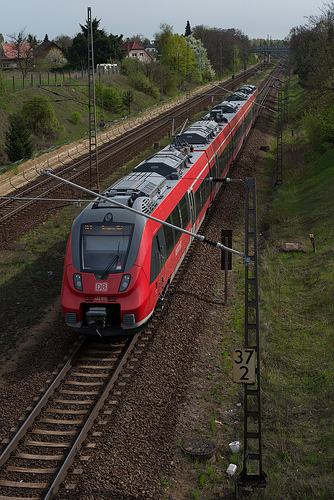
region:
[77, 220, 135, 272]
Windshield on a train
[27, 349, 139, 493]
Railroad track in the rocks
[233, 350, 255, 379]
Black numbers on a sign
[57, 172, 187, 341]
Front end of a train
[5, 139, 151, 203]
Railroad tracks in the rocks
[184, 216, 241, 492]
Patches of green grass in the dirt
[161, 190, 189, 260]
Windows on a train car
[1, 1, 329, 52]
Grayish skies overhead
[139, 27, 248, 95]
Group of trees lining the railroad tracks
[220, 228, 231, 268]
Back side of a sign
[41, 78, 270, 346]
train on the tracks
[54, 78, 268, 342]
five cars on the train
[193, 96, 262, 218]
row of dark windows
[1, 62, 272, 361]
grass between the two sets of train tracks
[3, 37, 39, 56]
roof of a house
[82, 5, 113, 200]
metal structure between the train tracks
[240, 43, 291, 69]
metal structure over the tracks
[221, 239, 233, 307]
pole sticking out of the dirt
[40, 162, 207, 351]
This is a train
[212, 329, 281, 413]
"372" on the sign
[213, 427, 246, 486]
Trash on the ground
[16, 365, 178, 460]
The train is using these tracks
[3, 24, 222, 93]
Houses in the background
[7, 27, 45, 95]
This tree barely has leaves on it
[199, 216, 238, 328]
A sign on the road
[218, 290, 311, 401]
Grass is poking out of the ground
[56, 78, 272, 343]
a passenger train travelling down the tracks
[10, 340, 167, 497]
the rails of a train track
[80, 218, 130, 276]
the windshield of a train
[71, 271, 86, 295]
the headlight of a train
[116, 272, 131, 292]
the headlight of a train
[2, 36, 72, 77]
a building on the hillside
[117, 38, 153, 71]
a building on the hillside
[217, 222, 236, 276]
the back of a train signal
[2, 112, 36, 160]
the foliage of a conifer tree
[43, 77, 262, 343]
a train is on the tracks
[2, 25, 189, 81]
houses are in the background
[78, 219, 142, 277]
the trains windshield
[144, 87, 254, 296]
the train is red and grey in color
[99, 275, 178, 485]
rocks are next to the tracks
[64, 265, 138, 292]
the trains lights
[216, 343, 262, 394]
a sign with numbers on it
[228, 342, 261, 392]
the numbers are 37 and 2